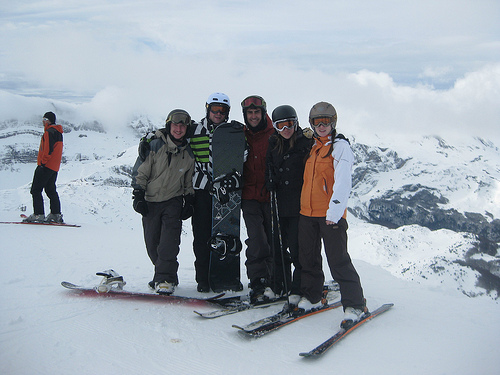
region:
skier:
[10, 91, 65, 238]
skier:
[284, 89, 391, 307]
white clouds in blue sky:
[388, 45, 430, 83]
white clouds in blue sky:
[388, 31, 442, 75]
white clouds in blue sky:
[310, 28, 384, 82]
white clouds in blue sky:
[257, 31, 307, 73]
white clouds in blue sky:
[220, 23, 307, 44]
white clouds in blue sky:
[141, 28, 203, 75]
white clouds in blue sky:
[87, 29, 135, 87]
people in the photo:
[43, 63, 420, 306]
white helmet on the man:
[194, 81, 246, 118]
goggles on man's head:
[197, 97, 235, 125]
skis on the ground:
[234, 282, 386, 374]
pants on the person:
[116, 193, 192, 275]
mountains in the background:
[378, 139, 470, 234]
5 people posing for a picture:
[105, 85, 370, 329]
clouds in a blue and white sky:
[350, 12, 497, 115]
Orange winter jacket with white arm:
[297, 127, 342, 217]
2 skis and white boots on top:
[232, 271, 399, 363]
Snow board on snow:
[65, 263, 244, 314]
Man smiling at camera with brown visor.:
[156, 107, 198, 147]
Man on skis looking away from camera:
[3, 101, 81, 241]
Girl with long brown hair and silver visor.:
[265, 107, 310, 169]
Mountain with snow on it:
[370, 139, 444, 239]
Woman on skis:
[235, 289, 394, 367]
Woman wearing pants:
[287, 207, 379, 311]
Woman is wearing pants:
[292, 206, 369, 313]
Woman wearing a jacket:
[300, 135, 360, 221]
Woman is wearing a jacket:
[297, 131, 354, 221]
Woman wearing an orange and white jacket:
[300, 132, 357, 223]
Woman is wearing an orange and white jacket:
[297, 130, 356, 225]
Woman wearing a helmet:
[306, 98, 339, 129]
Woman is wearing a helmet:
[308, 97, 338, 129]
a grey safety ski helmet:
[308, 100, 338, 141]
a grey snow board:
[208, 122, 249, 294]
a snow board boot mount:
[209, 233, 242, 263]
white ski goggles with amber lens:
[271, 117, 297, 133]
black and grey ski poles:
[261, 162, 295, 316]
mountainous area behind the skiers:
[368, 127, 498, 301]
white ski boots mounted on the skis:
[298, 297, 326, 313]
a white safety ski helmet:
[204, 92, 232, 112]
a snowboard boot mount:
[94, 268, 126, 293]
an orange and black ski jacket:
[36, 125, 66, 172]